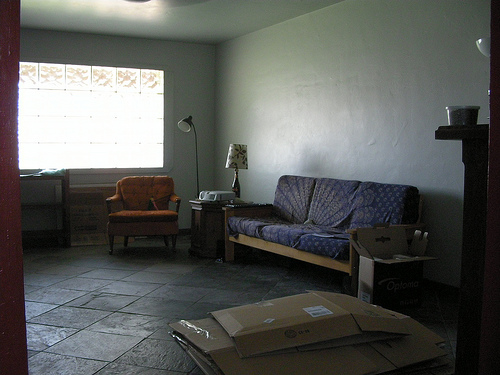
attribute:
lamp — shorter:
[221, 140, 250, 199]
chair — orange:
[100, 170, 184, 255]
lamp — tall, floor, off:
[174, 105, 204, 259]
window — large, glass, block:
[18, 62, 168, 175]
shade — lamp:
[223, 138, 250, 174]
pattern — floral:
[227, 145, 247, 170]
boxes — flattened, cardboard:
[154, 281, 445, 372]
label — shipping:
[303, 301, 332, 321]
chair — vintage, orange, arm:
[102, 170, 193, 255]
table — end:
[182, 196, 241, 256]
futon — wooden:
[226, 167, 417, 307]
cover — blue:
[257, 182, 363, 243]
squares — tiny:
[18, 66, 165, 167]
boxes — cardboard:
[170, 282, 469, 372]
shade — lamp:
[224, 143, 252, 180]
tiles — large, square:
[20, 246, 469, 372]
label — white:
[304, 299, 337, 323]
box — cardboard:
[205, 289, 415, 350]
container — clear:
[438, 102, 486, 130]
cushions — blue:
[231, 166, 416, 261]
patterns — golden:
[281, 179, 344, 219]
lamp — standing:
[173, 110, 203, 199]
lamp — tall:
[175, 111, 207, 245]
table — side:
[191, 199, 241, 254]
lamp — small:
[221, 138, 259, 205]